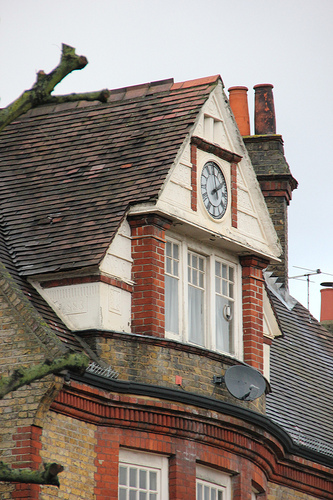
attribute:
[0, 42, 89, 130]
tree branch — green tree 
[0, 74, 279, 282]
roof — multicolored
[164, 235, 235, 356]
window — large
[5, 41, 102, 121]
branches — tree, green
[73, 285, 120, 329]
wall — crisp, white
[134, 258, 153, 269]
brick — large, building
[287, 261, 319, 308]
antenna — large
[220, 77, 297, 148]
cones — cylinder shaped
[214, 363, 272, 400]
dish — black, satellite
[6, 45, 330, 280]
roof — aluminium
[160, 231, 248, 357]
windows — triple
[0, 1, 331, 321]
sky — clear, gray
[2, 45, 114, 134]
pole — dried, wooden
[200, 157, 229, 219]
clock — round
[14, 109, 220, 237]
roof — shingled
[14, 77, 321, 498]
house — english, old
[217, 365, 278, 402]
dish — satellite, grey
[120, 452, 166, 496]
window — white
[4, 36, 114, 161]
branch — tree, cut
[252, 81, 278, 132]
chimney — brick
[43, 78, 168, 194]
top — roof